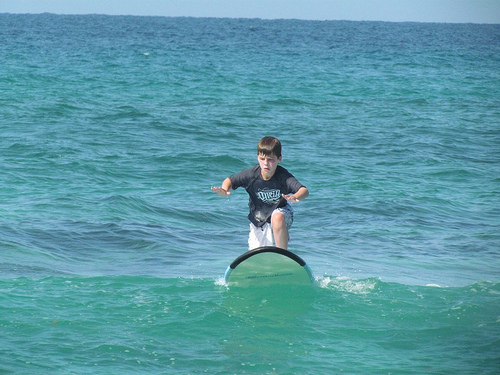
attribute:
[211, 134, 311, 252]
boy — wet, little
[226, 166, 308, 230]
t-shirt — grey, black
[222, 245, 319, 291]
surfboard — white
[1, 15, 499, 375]
water — blue, wavy, ripply, engaging, zealous, large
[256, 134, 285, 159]
hair — short, wet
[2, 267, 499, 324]
wave — small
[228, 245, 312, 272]
border — black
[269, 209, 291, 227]
knee — bent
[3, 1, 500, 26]
sky — blue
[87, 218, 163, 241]
ripple — small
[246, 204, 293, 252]
shorts — white